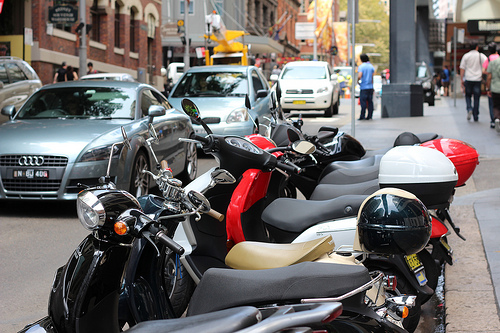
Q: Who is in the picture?
A: People walking on the streets.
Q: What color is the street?
A: Grey.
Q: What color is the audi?
A: Silver.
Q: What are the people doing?
A: Walking the street.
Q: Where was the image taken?
A: On a city street.